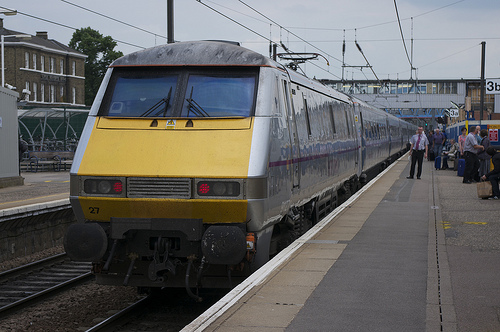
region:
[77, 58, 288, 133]
A glass windshield of a train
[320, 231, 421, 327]
A gray concrete ground surface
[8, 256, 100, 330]
Metal railroad tracks and gravel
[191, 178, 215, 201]
A red light on a train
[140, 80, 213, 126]
Windshield wipers on a train's windshield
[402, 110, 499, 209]
A group of people at at train station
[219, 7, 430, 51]
Electrical wires above a train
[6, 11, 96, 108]
A brown brick building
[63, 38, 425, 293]
Train on the tracks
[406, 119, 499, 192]
People in the background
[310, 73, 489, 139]
Building in the background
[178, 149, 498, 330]
Long flat paved pavillion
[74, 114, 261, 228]
Yellow face of an engine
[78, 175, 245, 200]
Front lights of an engine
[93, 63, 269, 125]
Front windscrean with wipers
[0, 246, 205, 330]
Rails on the track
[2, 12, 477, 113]
Maze of overhead cables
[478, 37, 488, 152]
Tall black thin pole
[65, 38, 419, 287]
a train is stopped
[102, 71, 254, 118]
front windows of train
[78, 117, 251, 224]
front is painted yellow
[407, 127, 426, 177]
a man is standing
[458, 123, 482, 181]
people standing around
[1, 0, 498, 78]
cables in the air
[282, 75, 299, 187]
the door is closed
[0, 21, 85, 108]
building is brown and white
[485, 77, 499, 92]
the sign says 3b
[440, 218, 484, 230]
yellow marks on ground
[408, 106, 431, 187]
this is a person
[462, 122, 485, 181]
this is a person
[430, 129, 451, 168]
this is a person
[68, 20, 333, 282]
this is a train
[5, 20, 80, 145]
this is a building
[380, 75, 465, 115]
this is a building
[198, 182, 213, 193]
this is a red light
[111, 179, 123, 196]
this is a red light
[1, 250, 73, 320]
this is the rail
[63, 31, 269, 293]
front car of commuter train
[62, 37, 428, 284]
commuter train at platform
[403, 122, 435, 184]
man with short sleeved shirt and red tie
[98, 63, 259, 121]
windshield of commuter train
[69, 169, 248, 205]
headlight and tail light of commuter train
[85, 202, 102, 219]
number 27 in black on yellow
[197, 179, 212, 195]
red tail light circle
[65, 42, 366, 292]
first car of commuter train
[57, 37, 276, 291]
front of commuter train with yellow panel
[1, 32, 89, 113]
brick multistory builing with white window frames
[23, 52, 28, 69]
A window on a building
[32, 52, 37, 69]
A window on a building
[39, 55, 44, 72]
A window on a building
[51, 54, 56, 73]
A window on a building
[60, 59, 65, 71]
A window on a building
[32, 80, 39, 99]
A window on a building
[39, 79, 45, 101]
A window on a building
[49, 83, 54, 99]
A window on a building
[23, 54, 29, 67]
A window on the side of a building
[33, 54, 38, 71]
A window on the side of a building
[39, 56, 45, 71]
A window on the side of a building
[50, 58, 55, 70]
A window on the side of a building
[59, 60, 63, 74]
A window on the side of a building